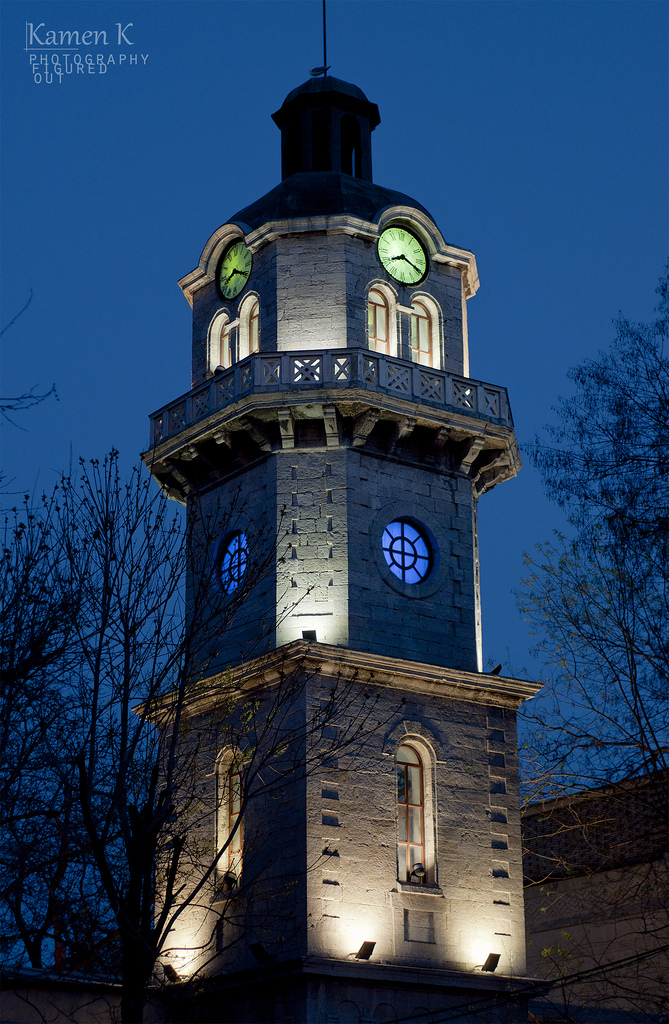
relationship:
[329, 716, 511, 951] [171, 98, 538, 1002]
wall of the building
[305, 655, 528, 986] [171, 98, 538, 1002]
wall of a building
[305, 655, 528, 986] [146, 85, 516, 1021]
wall of a building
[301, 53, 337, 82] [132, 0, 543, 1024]
bird on the building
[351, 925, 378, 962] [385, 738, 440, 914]
light mounted in window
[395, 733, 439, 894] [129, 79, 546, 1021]
window on building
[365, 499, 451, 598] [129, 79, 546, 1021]
window on building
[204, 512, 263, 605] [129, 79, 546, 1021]
window on building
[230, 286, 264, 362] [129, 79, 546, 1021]
window on building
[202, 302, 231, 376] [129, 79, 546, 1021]
window on building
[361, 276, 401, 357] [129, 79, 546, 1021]
window on building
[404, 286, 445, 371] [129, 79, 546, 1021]
window on building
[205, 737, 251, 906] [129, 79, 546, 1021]
window on building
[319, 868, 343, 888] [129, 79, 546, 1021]
square on building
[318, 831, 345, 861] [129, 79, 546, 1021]
square on building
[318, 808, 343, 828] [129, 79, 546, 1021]
square on building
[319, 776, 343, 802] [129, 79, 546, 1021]
square on building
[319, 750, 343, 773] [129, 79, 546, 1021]
square on building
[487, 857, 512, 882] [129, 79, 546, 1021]
square on building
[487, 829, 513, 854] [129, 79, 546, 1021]
square on building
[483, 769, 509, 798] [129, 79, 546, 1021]
square on building